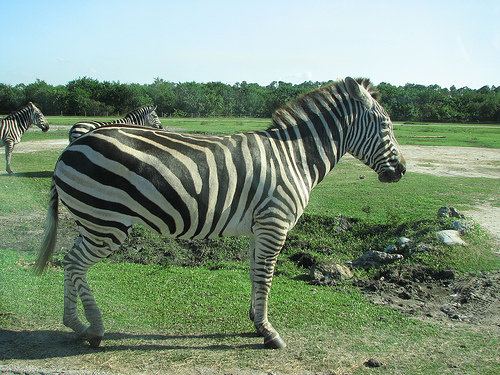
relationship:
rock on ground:
[345, 236, 415, 274] [5, 110, 494, 373]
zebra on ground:
[34, 74, 411, 350] [5, 110, 494, 373]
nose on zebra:
[382, 157, 406, 190] [34, 74, 411, 350]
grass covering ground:
[341, 183, 386, 217] [5, 110, 494, 373]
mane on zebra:
[267, 77, 377, 127] [34, 74, 411, 350]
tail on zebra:
[31, 180, 59, 280] [34, 74, 411, 350]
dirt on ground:
[365, 264, 499, 324] [5, 110, 494, 373]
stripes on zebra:
[135, 148, 278, 220] [34, 74, 411, 350]